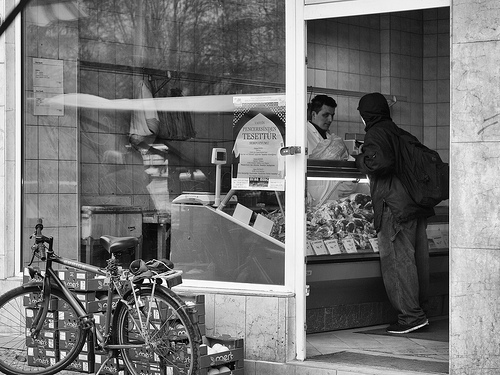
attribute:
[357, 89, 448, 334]
man — looking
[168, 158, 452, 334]
counter — glass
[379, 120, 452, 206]
backpack — black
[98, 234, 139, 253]
seat — black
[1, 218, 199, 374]
bike — parked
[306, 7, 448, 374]
doorway — open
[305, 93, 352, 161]
man — standing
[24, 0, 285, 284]
window — glass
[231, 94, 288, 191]
sign — posted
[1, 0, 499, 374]
photo — black, white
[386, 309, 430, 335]
shoe — black